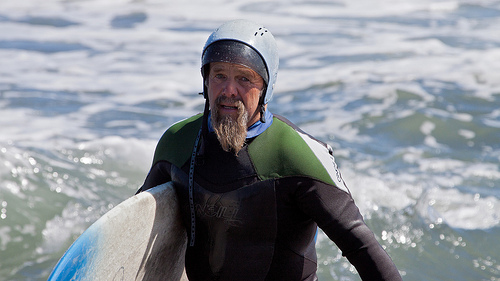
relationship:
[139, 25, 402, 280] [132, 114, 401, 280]
man wearing wetsuit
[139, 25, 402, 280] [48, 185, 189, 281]
man holding surfboard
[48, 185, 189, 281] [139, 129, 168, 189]
surfboard under arm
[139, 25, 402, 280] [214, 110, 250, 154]
man has beard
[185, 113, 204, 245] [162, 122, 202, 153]
strap on shoulder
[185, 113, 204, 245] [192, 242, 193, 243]
strap hanging down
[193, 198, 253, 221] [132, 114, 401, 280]
logo on wetsuit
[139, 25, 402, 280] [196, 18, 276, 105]
man wears helmet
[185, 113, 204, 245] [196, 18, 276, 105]
strap from helmet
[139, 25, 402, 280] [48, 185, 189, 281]
man carrying surfboard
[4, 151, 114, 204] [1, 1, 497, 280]
reflection on water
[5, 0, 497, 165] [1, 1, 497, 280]
white on water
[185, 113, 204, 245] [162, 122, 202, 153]
strap over shoulder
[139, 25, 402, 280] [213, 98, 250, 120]
man has mustache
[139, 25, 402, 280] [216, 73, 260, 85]
man has blue eyes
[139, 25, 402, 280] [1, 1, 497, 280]
man in water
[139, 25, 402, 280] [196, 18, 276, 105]
man has helmet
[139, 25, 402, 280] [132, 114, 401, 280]
man has wetsuit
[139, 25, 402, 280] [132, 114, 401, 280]
man in wetsuit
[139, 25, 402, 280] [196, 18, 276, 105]
man wearing helmet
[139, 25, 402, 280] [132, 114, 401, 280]
man wears wetsuit